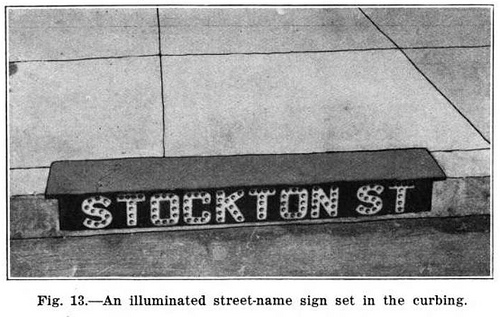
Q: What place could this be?
A: It is a sidewalk.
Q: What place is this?
A: It is a sidewalk.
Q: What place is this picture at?
A: It is at the sidewalk.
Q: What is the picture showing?
A: It is showing a sidewalk.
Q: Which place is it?
A: It is a sidewalk.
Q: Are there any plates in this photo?
A: Yes, there is a plate.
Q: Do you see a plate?
A: Yes, there is a plate.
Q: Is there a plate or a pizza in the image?
A: Yes, there is a plate.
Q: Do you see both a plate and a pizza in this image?
A: No, there is a plate but no pizzas.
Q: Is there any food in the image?
A: No, there is no food.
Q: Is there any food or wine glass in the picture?
A: No, there are no food or wine glasses.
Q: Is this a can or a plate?
A: This is a plate.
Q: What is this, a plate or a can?
A: This is a plate.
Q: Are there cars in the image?
A: No, there are no cars.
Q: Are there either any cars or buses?
A: No, there are no cars or buses.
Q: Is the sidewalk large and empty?
A: Yes, the sidewalk is large and empty.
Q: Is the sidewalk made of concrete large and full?
A: No, the side walk is large but empty.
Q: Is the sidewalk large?
A: Yes, the sidewalk is large.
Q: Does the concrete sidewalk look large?
A: Yes, the sidewalk is large.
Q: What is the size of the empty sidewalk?
A: The sidewalk is large.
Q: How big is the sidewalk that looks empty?
A: The side walk is large.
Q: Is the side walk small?
A: No, the side walk is large.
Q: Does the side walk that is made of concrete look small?
A: No, the sidewalk is large.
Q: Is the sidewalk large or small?
A: The sidewalk is large.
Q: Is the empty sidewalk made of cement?
A: Yes, the side walk is made of cement.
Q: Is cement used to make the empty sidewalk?
A: Yes, the side walk is made of cement.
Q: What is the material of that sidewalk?
A: The sidewalk is made of concrete.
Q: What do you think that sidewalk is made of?
A: The sidewalk is made of concrete.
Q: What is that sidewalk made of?
A: The sidewalk is made of concrete.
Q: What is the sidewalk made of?
A: The sidewalk is made of concrete.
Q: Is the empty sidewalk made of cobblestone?
A: No, the sidewalk is made of concrete.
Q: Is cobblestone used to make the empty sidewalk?
A: No, the sidewalk is made of concrete.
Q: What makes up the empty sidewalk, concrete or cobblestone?
A: The side walk is made of concrete.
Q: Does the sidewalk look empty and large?
A: Yes, the sidewalk is empty and large.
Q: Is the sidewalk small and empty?
A: No, the sidewalk is empty but large.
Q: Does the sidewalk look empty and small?
A: No, the sidewalk is empty but large.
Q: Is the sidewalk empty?
A: Yes, the sidewalk is empty.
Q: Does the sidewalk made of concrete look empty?
A: Yes, the sidewalk is empty.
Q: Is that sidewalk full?
A: No, the sidewalk is empty.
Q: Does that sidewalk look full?
A: No, the sidewalk is empty.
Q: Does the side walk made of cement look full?
A: No, the sidewalk is empty.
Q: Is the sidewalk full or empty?
A: The sidewalk is empty.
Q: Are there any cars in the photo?
A: No, there are no cars.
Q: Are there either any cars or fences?
A: No, there are no cars or fences.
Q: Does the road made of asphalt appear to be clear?
A: Yes, the road is clear.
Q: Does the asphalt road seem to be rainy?
A: No, the road is clear.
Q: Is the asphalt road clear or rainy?
A: The road is clear.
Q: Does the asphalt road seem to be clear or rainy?
A: The road is clear.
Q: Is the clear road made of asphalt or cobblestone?
A: The road is made of asphalt.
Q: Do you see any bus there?
A: No, there are no buses.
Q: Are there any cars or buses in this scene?
A: No, there are no buses or cars.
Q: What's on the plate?
A: The word is on the plate.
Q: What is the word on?
A: The word is on the plate.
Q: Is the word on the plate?
A: Yes, the word is on the plate.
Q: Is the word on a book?
A: No, the word is on the plate.